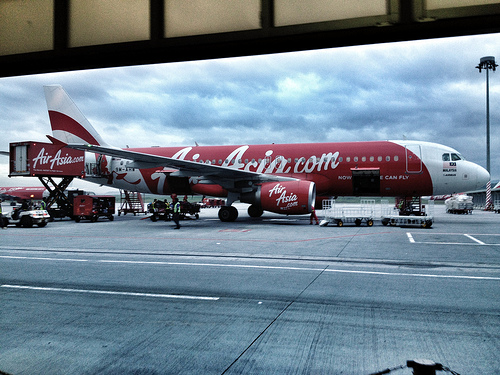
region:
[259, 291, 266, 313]
white mark is spotted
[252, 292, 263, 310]
white mark is spotted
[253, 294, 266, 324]
white mark is spotted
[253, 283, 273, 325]
white mark is spotted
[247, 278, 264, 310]
white mark is spotted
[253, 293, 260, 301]
white mark is spotted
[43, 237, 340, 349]
Gray pavement on a runway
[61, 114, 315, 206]
Wing on a plane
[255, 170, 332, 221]
Engine on a plane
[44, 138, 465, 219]
Red and white airplane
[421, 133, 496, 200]
Nose on a plane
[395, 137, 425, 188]
Door on a plane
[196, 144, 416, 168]
Windows on a plane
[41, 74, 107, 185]
Tail on a plane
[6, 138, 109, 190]
Liftt next to a plane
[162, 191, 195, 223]
Man on a runway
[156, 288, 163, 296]
the line is white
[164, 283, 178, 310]
the line is white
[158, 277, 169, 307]
the line is white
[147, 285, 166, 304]
the line is white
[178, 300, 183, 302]
the line is white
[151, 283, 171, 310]
the line is white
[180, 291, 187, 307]
the line is white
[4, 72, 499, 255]
Air Asia airplane on the tarmack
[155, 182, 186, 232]
Airport worker standing near a plane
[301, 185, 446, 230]
Cart near an airplane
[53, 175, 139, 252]
Luggage cart full of luggage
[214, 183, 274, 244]
Wheels on an airplane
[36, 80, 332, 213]
Wing of an airplane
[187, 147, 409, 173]
Windows on the side of an airplane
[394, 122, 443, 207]
Door on an airplane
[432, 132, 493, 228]
Windshield on an airplane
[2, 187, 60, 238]
Motorized vehicle near an airplane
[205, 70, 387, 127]
The sky has clouds in it.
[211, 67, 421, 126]
The clouds are blue and white.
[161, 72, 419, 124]
The sky is full of clouds.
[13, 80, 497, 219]
The plane is large.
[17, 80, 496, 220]
The plane is red and white.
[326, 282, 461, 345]
The ground is gray.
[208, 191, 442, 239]
The plane has wheels.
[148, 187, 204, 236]
People are walking.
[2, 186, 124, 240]
Cars are in the background.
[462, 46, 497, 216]
A light pole.